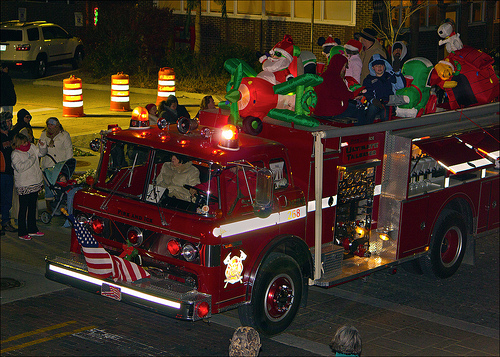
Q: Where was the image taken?
A: It was taken at the street.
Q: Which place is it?
A: It is a street.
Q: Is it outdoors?
A: Yes, it is outdoors.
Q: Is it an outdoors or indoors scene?
A: It is outdoors.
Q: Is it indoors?
A: No, it is outdoors.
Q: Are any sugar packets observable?
A: No, there are no sugar packets.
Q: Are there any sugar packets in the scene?
A: No, there are no sugar packets.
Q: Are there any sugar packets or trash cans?
A: No, there are no sugar packets or trash cans.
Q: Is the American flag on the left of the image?
A: Yes, the American flag is on the left of the image.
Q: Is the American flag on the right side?
A: No, the American flag is on the left of the image.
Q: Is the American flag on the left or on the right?
A: The American flag is on the left of the image.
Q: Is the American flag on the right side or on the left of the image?
A: The American flag is on the left of the image.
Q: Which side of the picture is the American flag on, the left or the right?
A: The American flag is on the left of the image.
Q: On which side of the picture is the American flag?
A: The American flag is on the left of the image.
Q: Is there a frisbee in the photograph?
A: No, there are no frisbees.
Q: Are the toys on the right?
A: Yes, the toys are on the right of the image.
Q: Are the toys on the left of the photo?
A: No, the toys are on the right of the image.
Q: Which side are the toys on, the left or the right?
A: The toys are on the right of the image.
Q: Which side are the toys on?
A: The toys are on the right of the image.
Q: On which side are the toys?
A: The toys are on the right of the image.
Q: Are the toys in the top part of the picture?
A: Yes, the toys are in the top of the image.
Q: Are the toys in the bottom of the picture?
A: No, the toys are in the top of the image.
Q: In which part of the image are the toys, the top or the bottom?
A: The toys are in the top of the image.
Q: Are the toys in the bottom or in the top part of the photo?
A: The toys are in the top of the image.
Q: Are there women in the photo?
A: Yes, there is a woman.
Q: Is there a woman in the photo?
A: Yes, there is a woman.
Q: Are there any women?
A: Yes, there is a woman.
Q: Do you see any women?
A: Yes, there is a woman.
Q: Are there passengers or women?
A: Yes, there is a woman.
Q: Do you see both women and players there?
A: No, there is a woman but no players.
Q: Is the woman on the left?
A: Yes, the woman is on the left of the image.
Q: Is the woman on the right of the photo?
A: No, the woman is on the left of the image.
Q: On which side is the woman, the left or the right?
A: The woman is on the left of the image.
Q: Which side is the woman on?
A: The woman is on the left of the image.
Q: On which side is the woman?
A: The woman is on the left of the image.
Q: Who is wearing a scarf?
A: The woman is wearing a scarf.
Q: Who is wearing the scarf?
A: The woman is wearing a scarf.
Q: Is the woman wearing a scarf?
A: Yes, the woman is wearing a scarf.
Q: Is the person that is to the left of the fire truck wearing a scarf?
A: Yes, the woman is wearing a scarf.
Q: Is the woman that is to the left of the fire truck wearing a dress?
A: No, the woman is wearing a scarf.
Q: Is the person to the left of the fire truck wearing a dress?
A: No, the woman is wearing a scarf.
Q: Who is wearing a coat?
A: The woman is wearing a coat.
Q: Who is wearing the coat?
A: The woman is wearing a coat.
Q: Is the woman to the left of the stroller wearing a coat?
A: Yes, the woman is wearing a coat.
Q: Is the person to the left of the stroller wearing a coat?
A: Yes, the woman is wearing a coat.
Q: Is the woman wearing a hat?
A: No, the woman is wearing a coat.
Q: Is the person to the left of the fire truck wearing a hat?
A: No, the woman is wearing a coat.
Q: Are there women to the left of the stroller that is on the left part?
A: Yes, there is a woman to the left of the stroller.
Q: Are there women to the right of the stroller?
A: No, the woman is to the left of the stroller.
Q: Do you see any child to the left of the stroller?
A: No, there is a woman to the left of the stroller.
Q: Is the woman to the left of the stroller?
A: Yes, the woman is to the left of the stroller.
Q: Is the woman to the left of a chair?
A: No, the woman is to the left of the stroller.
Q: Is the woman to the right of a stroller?
A: No, the woman is to the left of a stroller.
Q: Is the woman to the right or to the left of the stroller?
A: The woman is to the left of the stroller.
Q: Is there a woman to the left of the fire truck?
A: Yes, there is a woman to the left of the fire truck.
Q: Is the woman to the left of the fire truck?
A: Yes, the woman is to the left of the fire truck.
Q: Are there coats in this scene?
A: Yes, there is a coat.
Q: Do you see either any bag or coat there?
A: Yes, there is a coat.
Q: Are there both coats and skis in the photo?
A: No, there is a coat but no skis.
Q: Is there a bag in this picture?
A: No, there are no bags.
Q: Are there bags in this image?
A: No, there are no bags.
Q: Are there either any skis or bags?
A: No, there are no bags or skis.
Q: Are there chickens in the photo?
A: No, there are no chickens.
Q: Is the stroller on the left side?
A: Yes, the stroller is on the left of the image.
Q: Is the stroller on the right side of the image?
A: No, the stroller is on the left of the image.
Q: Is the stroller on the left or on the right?
A: The stroller is on the left of the image.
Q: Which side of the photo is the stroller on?
A: The stroller is on the left of the image.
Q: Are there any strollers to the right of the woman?
A: Yes, there is a stroller to the right of the woman.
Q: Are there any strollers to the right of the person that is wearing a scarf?
A: Yes, there is a stroller to the right of the woman.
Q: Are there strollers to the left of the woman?
A: No, the stroller is to the right of the woman.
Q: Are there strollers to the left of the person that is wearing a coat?
A: No, the stroller is to the right of the woman.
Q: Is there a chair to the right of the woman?
A: No, there is a stroller to the right of the woman.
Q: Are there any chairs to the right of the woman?
A: No, there is a stroller to the right of the woman.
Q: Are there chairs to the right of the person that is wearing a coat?
A: No, there is a stroller to the right of the woman.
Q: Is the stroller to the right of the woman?
A: Yes, the stroller is to the right of the woman.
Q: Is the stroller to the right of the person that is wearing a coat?
A: Yes, the stroller is to the right of the woman.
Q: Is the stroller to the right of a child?
A: No, the stroller is to the right of the woman.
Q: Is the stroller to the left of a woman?
A: No, the stroller is to the right of a woman.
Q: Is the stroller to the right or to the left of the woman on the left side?
A: The stroller is to the right of the woman.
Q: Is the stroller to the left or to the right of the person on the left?
A: The stroller is to the right of the woman.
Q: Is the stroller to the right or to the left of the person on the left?
A: The stroller is to the right of the woman.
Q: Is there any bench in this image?
A: No, there are no benches.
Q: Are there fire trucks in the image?
A: Yes, there is a fire truck.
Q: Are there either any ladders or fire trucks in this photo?
A: Yes, there is a fire truck.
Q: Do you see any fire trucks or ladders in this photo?
A: Yes, there is a fire truck.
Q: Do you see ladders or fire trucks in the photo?
A: Yes, there is a fire truck.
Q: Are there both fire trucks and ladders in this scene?
A: No, there is a fire truck but no ladders.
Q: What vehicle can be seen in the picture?
A: The vehicle is a fire truck.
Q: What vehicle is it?
A: The vehicle is a fire truck.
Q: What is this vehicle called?
A: This is a fire truck.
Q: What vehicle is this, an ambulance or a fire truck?
A: This is a fire truck.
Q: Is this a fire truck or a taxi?
A: This is a fire truck.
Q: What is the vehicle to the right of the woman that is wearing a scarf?
A: The vehicle is a fire truck.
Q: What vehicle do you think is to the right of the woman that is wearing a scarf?
A: The vehicle is a fire truck.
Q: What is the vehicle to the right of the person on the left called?
A: The vehicle is a fire truck.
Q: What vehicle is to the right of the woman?
A: The vehicle is a fire truck.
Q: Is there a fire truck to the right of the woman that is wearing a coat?
A: Yes, there is a fire truck to the right of the woman.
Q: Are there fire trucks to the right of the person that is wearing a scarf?
A: Yes, there is a fire truck to the right of the woman.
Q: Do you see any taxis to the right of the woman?
A: No, there is a fire truck to the right of the woman.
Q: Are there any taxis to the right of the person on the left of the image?
A: No, there is a fire truck to the right of the woman.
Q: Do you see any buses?
A: No, there are no buses.